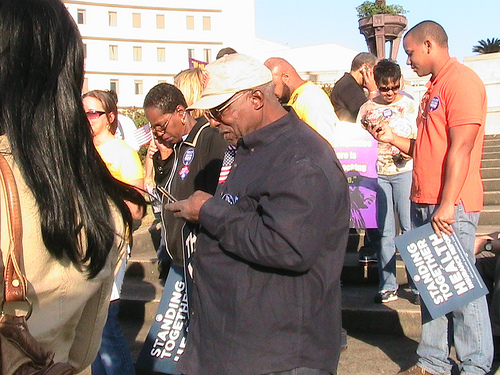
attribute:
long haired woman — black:
[0, 1, 141, 373]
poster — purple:
[330, 143, 381, 233]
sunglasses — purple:
[82, 106, 108, 128]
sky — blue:
[254, 2, 495, 58]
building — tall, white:
[51, 0, 256, 109]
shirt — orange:
[412, 56, 488, 216]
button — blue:
[429, 94, 440, 117]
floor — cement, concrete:
[116, 233, 497, 374]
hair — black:
[147, 82, 185, 111]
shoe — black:
[375, 287, 401, 308]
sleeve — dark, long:
[204, 197, 282, 266]